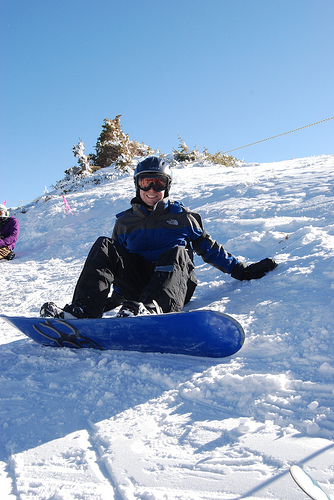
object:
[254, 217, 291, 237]
snow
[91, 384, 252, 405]
ground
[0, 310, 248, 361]
snowboard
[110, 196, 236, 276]
jacket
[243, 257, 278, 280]
glove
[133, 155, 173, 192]
helmet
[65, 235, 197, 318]
pants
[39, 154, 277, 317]
man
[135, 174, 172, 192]
goggles